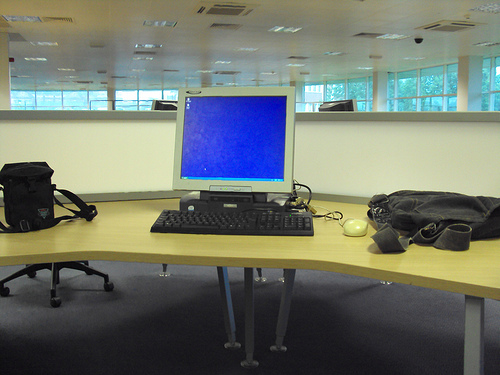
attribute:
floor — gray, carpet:
[1, 266, 498, 372]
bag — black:
[11, 163, 62, 235]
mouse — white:
[342, 202, 372, 257]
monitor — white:
[166, 95, 298, 200]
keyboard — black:
[145, 203, 332, 246]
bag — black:
[0, 158, 98, 235]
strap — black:
[0, 185, 97, 232]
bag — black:
[365, 192, 499, 254]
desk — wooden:
[0, 176, 497, 373]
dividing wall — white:
[1, 107, 498, 209]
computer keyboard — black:
[148, 205, 316, 239]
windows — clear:
[385, 55, 472, 115]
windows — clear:
[318, 68, 378, 95]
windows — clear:
[7, 80, 149, 107]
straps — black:
[368, 218, 474, 254]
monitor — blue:
[143, 52, 308, 211]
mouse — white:
[335, 214, 368, 239]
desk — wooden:
[0, 192, 497, 307]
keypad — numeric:
[282, 214, 310, 231]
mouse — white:
[343, 220, 368, 236]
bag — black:
[367, 186, 498, 254]